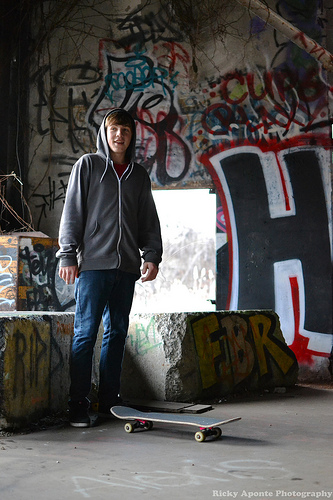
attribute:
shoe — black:
[64, 399, 100, 432]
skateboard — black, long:
[110, 403, 241, 444]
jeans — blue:
[69, 268, 140, 405]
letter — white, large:
[197, 125, 331, 338]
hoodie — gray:
[55, 103, 164, 267]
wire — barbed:
[0, 156, 44, 232]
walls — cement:
[90, 44, 330, 268]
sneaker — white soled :
[94, 398, 141, 421]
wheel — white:
[194, 431, 205, 444]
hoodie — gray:
[49, 92, 166, 279]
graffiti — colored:
[4, 0, 331, 353]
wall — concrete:
[170, 305, 297, 400]